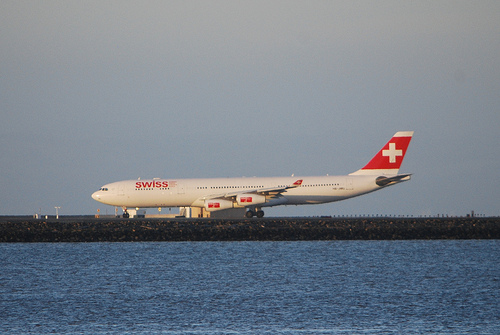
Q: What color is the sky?
A: Blue.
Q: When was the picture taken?
A: Daytime.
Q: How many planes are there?
A: One.